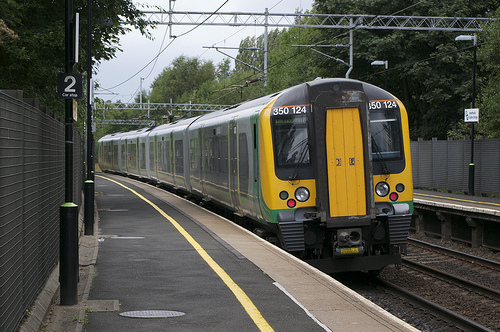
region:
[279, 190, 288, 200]
the front light of the train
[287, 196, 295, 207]
the front light of the train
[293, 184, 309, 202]
the front light of the train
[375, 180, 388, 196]
the front light of the train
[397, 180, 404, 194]
the front light of the train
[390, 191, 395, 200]
the front light of the train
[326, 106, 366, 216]
the door of the train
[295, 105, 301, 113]
the white number 2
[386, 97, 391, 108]
the white number 2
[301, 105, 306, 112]
the white number 4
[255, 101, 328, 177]
window of a train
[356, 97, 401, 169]
window of a train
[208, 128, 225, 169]
window of a train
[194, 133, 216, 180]
window of a train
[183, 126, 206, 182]
window of a train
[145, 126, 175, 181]
window of a train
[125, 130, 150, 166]
window of a train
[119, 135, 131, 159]
window of a train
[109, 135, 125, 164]
window of a train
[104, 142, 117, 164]
window of a train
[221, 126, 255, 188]
window of a train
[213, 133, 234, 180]
window of a train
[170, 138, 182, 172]
window of a train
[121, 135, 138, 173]
window of a train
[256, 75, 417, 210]
Bright yellow on the front of the train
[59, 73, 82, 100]
Number two on the pole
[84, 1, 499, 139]
Wires and poles make the train run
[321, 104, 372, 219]
Door on front of the train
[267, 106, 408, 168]
Windows for the conductor to see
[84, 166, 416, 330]
Platform for the passengers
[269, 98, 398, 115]
Number of the train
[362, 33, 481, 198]
Two lights for the passengers to see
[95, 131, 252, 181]
Lots of windows for the passengers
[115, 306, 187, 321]
Manhole cover on the platform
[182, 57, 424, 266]
a train on the track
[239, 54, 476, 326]
a train on the train track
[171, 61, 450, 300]
a passenger train on the track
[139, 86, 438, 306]
a passenger train on the train track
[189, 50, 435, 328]
a track with a train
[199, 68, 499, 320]
a train track with train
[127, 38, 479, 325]
a train with passenger train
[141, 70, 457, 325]
a train track with passenger train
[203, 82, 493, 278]
a train with yellow back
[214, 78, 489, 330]
a train with windows